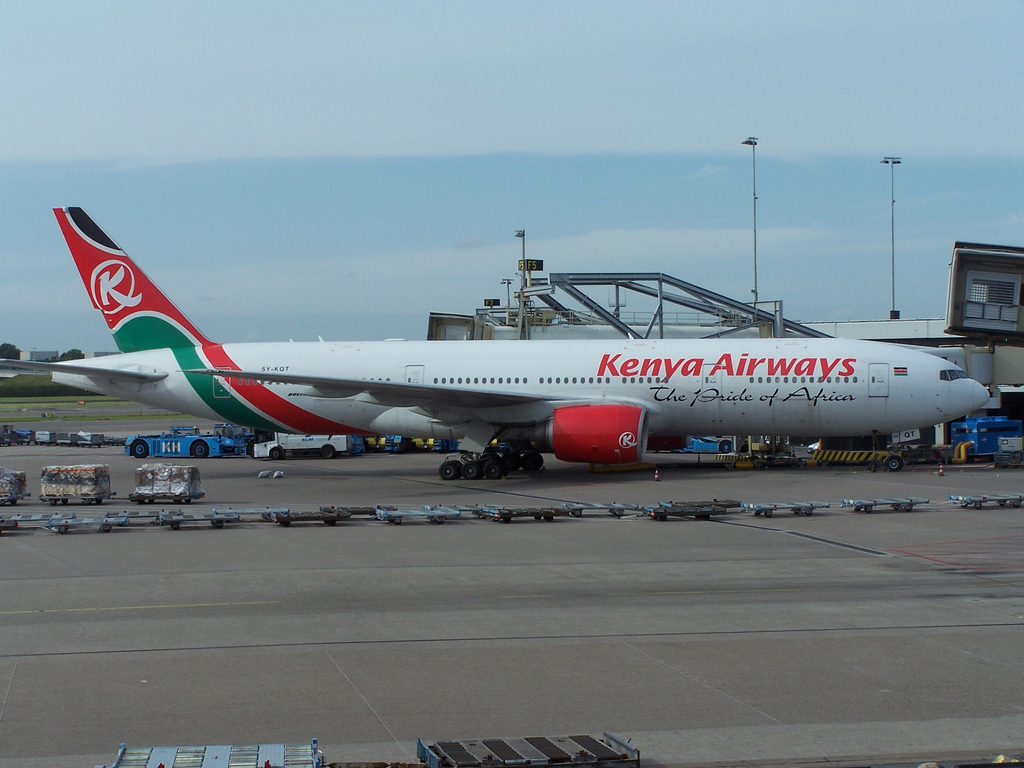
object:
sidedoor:
[351, 325, 446, 434]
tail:
[47, 196, 209, 469]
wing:
[25, 345, 160, 410]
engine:
[528, 395, 663, 478]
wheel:
[462, 456, 505, 483]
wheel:
[868, 430, 931, 478]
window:
[435, 376, 479, 387]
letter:
[618, 349, 646, 388]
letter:
[638, 354, 666, 385]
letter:
[659, 349, 683, 388]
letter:
[681, 350, 705, 380]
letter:
[701, 344, 737, 381]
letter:
[759, 350, 794, 380]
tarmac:
[11, 389, 989, 742]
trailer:
[747, 487, 835, 520]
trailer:
[372, 497, 463, 532]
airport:
[6, 35, 992, 725]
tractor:
[121, 418, 242, 466]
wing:
[172, 363, 657, 467]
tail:
[47, 197, 209, 338]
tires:
[432, 448, 549, 485]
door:
[859, 354, 898, 400]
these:
[11, 402, 465, 536]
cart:
[120, 424, 244, 472]